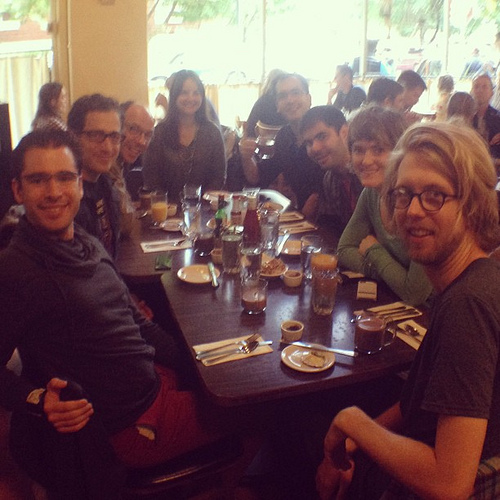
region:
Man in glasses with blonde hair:
[376, 122, 499, 498]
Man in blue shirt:
[1, 123, 89, 499]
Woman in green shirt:
[349, 107, 392, 285]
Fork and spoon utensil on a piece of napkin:
[190, 331, 274, 365]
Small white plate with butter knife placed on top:
[177, 260, 220, 285]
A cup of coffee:
[352, 309, 397, 354]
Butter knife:
[205, 259, 218, 289]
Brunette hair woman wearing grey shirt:
[143, 70, 227, 195]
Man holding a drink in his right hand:
[241, 73, 310, 194]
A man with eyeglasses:
[70, 95, 122, 235]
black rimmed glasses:
[385, 185, 464, 212]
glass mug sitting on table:
[352, 311, 397, 356]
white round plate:
[278, 338, 338, 375]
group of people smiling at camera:
[268, 68, 390, 197]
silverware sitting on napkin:
[192, 327, 274, 367]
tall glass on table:
[148, 186, 171, 236]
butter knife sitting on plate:
[204, 255, 221, 289]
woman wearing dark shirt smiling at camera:
[147, 66, 223, 195]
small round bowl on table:
[278, 319, 305, 341]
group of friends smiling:
[5, 91, 155, 498]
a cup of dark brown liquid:
[355, 312, 395, 351]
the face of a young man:
[12, 135, 85, 230]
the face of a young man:
[387, 128, 479, 265]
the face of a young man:
[70, 98, 122, 173]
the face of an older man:
[117, 101, 154, 164]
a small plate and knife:
[179, 263, 221, 288]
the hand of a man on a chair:
[43, 378, 93, 430]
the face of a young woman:
[351, 113, 390, 189]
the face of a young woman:
[172, 73, 203, 112]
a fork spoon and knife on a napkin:
[192, 328, 275, 368]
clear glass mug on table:
[350, 310, 395, 355]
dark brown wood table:
[160, 245, 427, 405]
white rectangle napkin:
[195, 330, 272, 365]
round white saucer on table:
[277, 340, 332, 370]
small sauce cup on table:
[280, 320, 305, 340]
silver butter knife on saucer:
[290, 335, 360, 355]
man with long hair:
[317, 115, 492, 495]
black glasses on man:
[381, 180, 466, 210]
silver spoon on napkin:
[195, 336, 260, 356]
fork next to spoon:
[196, 326, 262, 354]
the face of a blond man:
[384, 128, 495, 267]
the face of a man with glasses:
[12, 132, 87, 230]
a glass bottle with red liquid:
[244, 198, 259, 240]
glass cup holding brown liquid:
[238, 278, 270, 315]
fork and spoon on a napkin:
[191, 331, 273, 370]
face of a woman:
[171, 72, 201, 114]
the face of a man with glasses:
[73, 100, 120, 173]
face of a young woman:
[349, 121, 389, 188]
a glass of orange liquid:
[151, 190, 169, 224]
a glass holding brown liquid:
[352, 313, 396, 354]